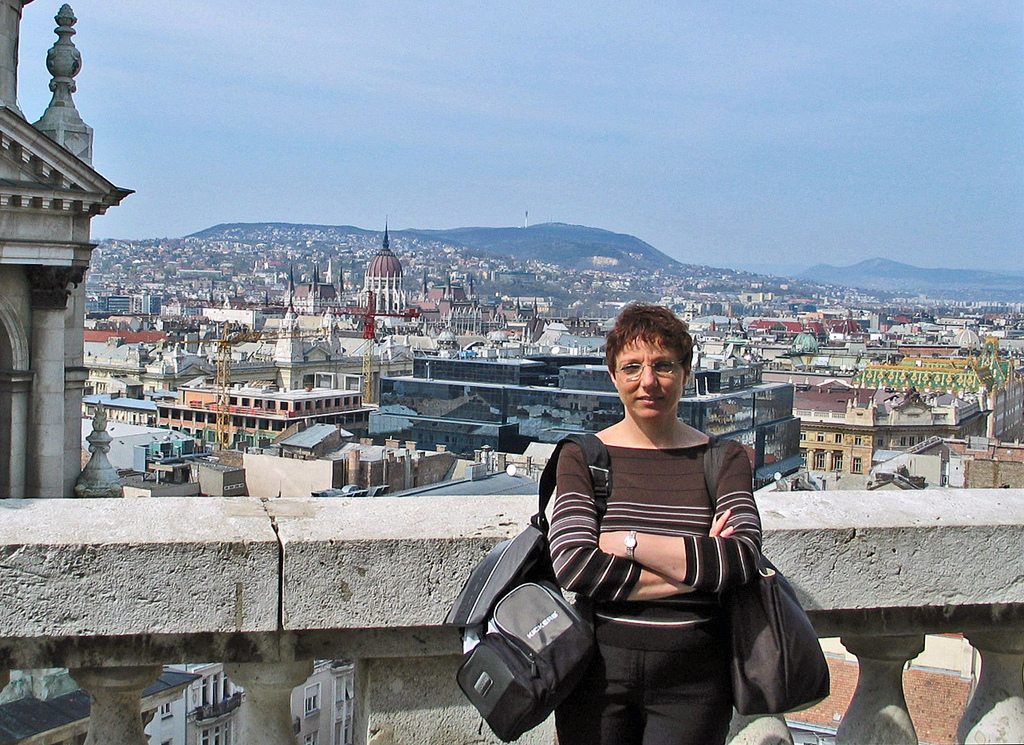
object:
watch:
[624, 531, 637, 561]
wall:
[369, 378, 500, 456]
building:
[368, 343, 804, 492]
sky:
[12, 0, 1023, 275]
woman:
[547, 301, 763, 745]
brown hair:
[605, 301, 693, 373]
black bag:
[442, 434, 610, 744]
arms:
[548, 511, 762, 601]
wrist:
[617, 531, 649, 567]